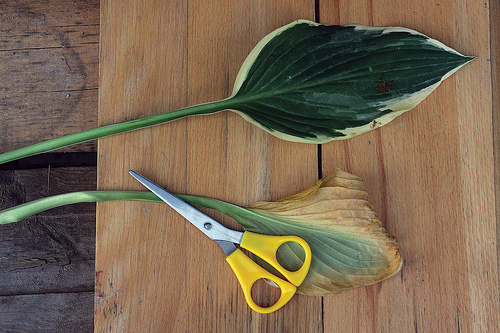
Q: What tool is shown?
A: Scissors.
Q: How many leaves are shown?
A: Two.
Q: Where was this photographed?
A: A table.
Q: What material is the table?
A: Wood.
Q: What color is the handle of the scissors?
A: Yellow.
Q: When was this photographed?
A: Daytime.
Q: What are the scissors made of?
A: Metal.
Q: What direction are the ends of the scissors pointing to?
A: Upper left.